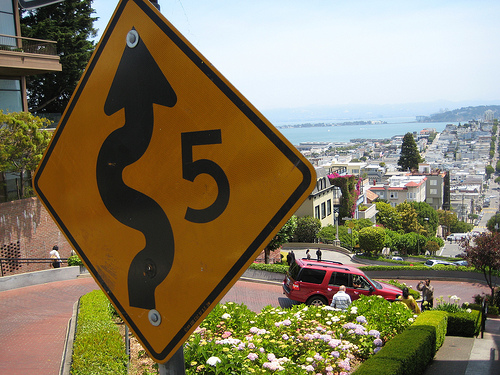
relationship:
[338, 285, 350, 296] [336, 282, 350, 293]
man head bald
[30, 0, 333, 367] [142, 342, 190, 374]
sign on post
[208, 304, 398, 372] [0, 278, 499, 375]
flowers by road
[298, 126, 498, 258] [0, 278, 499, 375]
city by road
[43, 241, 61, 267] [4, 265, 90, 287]
woman on sidewalk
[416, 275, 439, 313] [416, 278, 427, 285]
person taking picture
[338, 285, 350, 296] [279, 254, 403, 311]
man by suv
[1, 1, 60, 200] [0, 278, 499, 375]
building by road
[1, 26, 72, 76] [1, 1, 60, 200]
balcony on building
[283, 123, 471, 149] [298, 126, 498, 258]
ocean by city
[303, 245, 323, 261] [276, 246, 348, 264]
people on sidewalk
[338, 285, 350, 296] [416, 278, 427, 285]
man taking picture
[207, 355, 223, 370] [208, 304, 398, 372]
flower in field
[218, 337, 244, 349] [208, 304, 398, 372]
flower in field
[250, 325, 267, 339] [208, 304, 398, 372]
flower in field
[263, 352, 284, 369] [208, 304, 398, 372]
flower in field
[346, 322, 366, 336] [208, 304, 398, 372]
flower in field